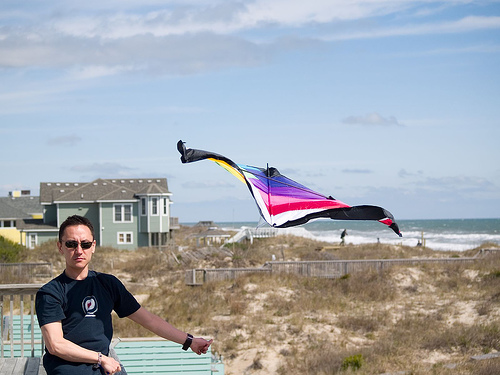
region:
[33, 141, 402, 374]
young man flying kite off of deck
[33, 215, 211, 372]
young man wearing sunglasses, blue tee shirt, dark pants and watch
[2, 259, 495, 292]
wooden walkway to beach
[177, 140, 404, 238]
red, pink,lavender, blue, white, yellow and black delta kite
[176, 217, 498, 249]
ocean with shore breaking waves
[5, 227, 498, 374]
sand dunes leading to ocean beach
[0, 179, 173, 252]
blue-gray two story beachfront home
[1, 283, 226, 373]
wooden deck with side railing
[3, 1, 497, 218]
Partly cloudy sky with high white and gray clouds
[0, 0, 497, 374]
kiteflying from the deck on a sunny day at the ocean shore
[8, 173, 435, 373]
a man flying a kite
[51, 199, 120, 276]
a man wearing sunglasses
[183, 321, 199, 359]
a man wearing a black wrist watch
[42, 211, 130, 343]
a man wearing a blue shirt with a logo on it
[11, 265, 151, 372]
a man sitting on a wood bench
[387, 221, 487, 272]
white waves in the ocean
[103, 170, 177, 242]
a green house with white trim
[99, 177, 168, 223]
a house with a shingled roof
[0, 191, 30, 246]
a yellow house with white trim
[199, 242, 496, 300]
a wood walkway leading to the beach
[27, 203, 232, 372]
person wearing sun glasses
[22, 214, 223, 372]
person wearing a navy blue shirt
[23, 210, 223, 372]
person wearing a watch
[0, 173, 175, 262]
a two story house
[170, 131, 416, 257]
a kite flown in the air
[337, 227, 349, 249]
person on the beach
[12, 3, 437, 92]
clouds in the sky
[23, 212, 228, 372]
person sitting on the bench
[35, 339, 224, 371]
a long blue bench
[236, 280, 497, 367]
a dry plain field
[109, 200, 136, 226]
the windows of a building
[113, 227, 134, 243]
the windows of a building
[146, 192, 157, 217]
the window of a building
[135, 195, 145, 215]
the window of a building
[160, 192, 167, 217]
the window of a building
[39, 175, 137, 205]
the roof of a building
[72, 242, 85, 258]
the nose of a building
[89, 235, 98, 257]
the ear of a man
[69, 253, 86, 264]
the mouth of a man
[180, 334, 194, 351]
a black mens wristwatch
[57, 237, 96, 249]
a pair of dark shades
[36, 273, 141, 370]
a dark short sleeve shirt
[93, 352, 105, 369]
a light colored wristband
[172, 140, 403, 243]
a multi-colored kite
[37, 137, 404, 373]
person holding a kite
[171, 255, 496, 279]
a wooden walkway to the beach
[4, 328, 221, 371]
a light blue wooden bench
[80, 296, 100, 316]
logo on dark tee shirt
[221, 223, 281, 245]
a set of white stairs and peer